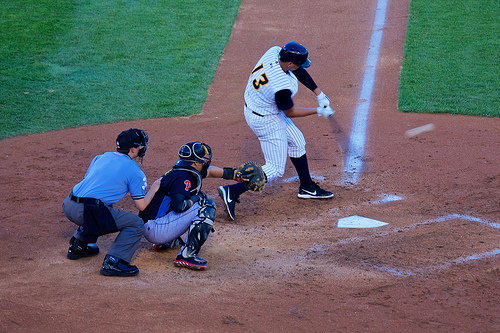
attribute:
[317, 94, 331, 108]
glove — white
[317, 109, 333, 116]
glove — white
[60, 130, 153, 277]
umpire — crouched, waiting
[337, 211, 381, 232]
plate — home, white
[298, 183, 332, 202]
shoe — black, nike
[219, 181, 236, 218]
shoe — black, nike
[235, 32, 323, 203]
player — batter, swinging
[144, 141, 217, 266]
catcher — ready, waiting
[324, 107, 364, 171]
bat — swinging, moving, swung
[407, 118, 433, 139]
ball — moving, heading, mid air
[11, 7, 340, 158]
territory — foul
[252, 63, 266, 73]
number — 1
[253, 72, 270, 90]
number — 3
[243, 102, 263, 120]
belt — black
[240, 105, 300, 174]
pants — striped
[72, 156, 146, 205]
shirt — blue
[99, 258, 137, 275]
shoe — black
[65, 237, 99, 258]
shoe — black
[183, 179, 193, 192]
p — red